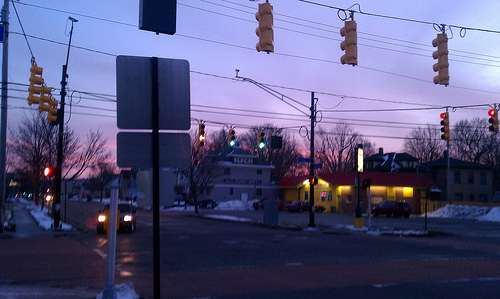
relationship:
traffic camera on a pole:
[61, 12, 79, 68] [55, 59, 66, 230]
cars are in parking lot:
[251, 195, 412, 219] [206, 201, 416, 230]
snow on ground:
[422, 201, 500, 222] [6, 197, 499, 299]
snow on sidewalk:
[20, 193, 73, 232] [6, 192, 74, 238]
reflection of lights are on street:
[95, 231, 137, 279] [6, 197, 499, 299]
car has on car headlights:
[97, 202, 137, 237] [97, 210, 132, 226]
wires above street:
[8, 0, 498, 105] [6, 197, 499, 299]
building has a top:
[278, 171, 428, 218] [277, 172, 434, 190]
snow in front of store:
[422, 201, 500, 222] [278, 171, 428, 218]